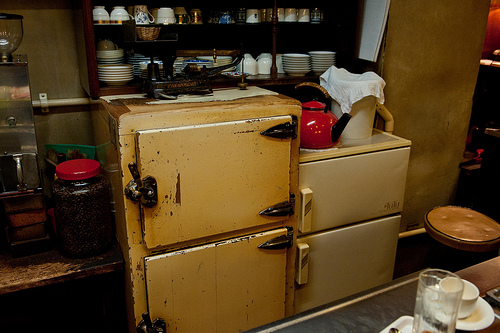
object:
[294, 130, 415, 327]
fridge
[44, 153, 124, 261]
jar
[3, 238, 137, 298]
counter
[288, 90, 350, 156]
teapot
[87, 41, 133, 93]
dishes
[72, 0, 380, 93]
shelf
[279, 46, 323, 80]
plates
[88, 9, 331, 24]
teacups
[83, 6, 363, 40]
cupboard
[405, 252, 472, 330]
glass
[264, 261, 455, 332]
counter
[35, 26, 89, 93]
wall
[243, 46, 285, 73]
bowels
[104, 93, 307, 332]
refrigerator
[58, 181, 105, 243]
beans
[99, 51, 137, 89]
stack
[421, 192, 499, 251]
seat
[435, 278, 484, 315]
cup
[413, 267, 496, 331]
saucer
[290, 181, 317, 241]
latch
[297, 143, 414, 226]
freezer door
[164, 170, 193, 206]
rust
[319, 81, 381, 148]
container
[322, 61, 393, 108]
dishcloth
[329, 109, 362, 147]
spout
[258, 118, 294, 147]
hinge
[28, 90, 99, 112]
pipe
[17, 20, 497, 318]
kitchen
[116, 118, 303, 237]
door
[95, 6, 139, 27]
coffe cup